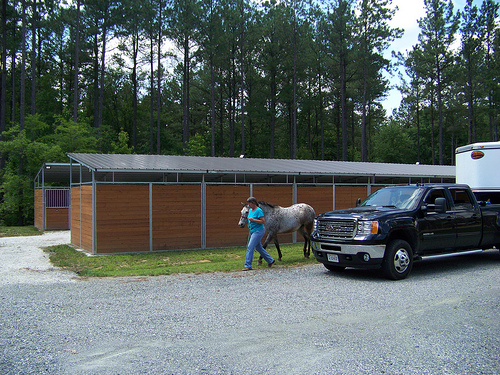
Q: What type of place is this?
A: It is a road.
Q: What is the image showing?
A: It is showing a road.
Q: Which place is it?
A: It is a road.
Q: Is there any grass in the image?
A: Yes, there is grass.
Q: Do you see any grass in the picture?
A: Yes, there is grass.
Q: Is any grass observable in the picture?
A: Yes, there is grass.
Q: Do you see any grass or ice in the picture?
A: Yes, there is grass.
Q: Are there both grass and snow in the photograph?
A: No, there is grass but no snow.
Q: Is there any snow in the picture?
A: No, there is no snow.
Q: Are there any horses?
A: Yes, there is a horse.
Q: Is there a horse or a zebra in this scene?
A: Yes, there is a horse.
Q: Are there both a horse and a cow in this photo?
A: No, there is a horse but no cows.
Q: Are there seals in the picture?
A: No, there are no seals.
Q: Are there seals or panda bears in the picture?
A: No, there are no seals or panda bears.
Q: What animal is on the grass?
A: The animal is a horse.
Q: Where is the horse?
A: The horse is on the grass.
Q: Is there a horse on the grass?
A: Yes, there is a horse on the grass.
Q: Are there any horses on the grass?
A: Yes, there is a horse on the grass.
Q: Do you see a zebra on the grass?
A: No, there is a horse on the grass.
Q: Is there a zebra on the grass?
A: No, there is a horse on the grass.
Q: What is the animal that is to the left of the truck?
A: The animal is a horse.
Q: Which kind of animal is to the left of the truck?
A: The animal is a horse.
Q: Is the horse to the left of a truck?
A: Yes, the horse is to the left of a truck.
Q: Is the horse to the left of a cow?
A: No, the horse is to the left of a truck.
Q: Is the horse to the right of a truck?
A: No, the horse is to the left of a truck.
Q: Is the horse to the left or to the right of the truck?
A: The horse is to the left of the truck.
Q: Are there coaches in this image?
A: No, there are no coaches.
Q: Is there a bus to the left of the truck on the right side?
A: No, there is a man to the left of the truck.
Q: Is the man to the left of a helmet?
A: No, the man is to the left of the truck.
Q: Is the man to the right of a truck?
A: No, the man is to the left of a truck.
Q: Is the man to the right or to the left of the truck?
A: The man is to the left of the truck.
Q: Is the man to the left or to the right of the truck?
A: The man is to the left of the truck.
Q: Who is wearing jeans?
A: The man is wearing jeans.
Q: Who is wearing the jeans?
A: The man is wearing jeans.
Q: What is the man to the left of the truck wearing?
A: The man is wearing jeans.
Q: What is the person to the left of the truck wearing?
A: The man is wearing jeans.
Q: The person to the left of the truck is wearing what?
A: The man is wearing jeans.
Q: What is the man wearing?
A: The man is wearing jeans.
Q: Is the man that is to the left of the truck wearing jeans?
A: Yes, the man is wearing jeans.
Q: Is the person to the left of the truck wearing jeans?
A: Yes, the man is wearing jeans.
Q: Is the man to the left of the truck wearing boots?
A: No, the man is wearing jeans.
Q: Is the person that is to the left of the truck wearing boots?
A: No, the man is wearing jeans.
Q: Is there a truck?
A: Yes, there is a truck.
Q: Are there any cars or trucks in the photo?
A: Yes, there is a truck.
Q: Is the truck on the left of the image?
A: No, the truck is on the right of the image.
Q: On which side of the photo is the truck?
A: The truck is on the right of the image.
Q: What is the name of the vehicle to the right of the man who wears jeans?
A: The vehicle is a truck.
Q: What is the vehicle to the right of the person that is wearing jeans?
A: The vehicle is a truck.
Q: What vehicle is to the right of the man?
A: The vehicle is a truck.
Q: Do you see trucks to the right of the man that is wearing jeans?
A: Yes, there is a truck to the right of the man.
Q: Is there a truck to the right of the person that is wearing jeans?
A: Yes, there is a truck to the right of the man.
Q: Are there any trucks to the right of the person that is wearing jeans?
A: Yes, there is a truck to the right of the man.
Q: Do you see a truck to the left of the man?
A: No, the truck is to the right of the man.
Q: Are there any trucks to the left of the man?
A: No, the truck is to the right of the man.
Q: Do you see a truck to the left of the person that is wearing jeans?
A: No, the truck is to the right of the man.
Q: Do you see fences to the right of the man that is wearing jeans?
A: No, there is a truck to the right of the man.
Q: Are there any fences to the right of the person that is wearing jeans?
A: No, there is a truck to the right of the man.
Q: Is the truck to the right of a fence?
A: No, the truck is to the right of a man.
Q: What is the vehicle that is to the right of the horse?
A: The vehicle is a truck.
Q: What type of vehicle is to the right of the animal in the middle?
A: The vehicle is a truck.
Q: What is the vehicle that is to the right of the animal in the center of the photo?
A: The vehicle is a truck.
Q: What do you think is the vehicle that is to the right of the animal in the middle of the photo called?
A: The vehicle is a truck.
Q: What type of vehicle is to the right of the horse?
A: The vehicle is a truck.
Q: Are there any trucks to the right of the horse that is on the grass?
A: Yes, there is a truck to the right of the horse.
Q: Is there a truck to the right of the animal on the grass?
A: Yes, there is a truck to the right of the horse.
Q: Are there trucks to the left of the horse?
A: No, the truck is to the right of the horse.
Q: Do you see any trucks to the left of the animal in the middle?
A: No, the truck is to the right of the horse.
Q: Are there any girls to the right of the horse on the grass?
A: No, there is a truck to the right of the horse.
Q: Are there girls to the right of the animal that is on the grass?
A: No, there is a truck to the right of the horse.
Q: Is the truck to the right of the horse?
A: Yes, the truck is to the right of the horse.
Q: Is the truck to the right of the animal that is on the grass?
A: Yes, the truck is to the right of the horse.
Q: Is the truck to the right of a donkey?
A: No, the truck is to the right of the horse.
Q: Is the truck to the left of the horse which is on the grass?
A: No, the truck is to the right of the horse.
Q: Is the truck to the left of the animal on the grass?
A: No, the truck is to the right of the horse.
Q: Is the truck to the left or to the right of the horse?
A: The truck is to the right of the horse.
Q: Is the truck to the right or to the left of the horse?
A: The truck is to the right of the horse.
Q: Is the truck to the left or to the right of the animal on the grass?
A: The truck is to the right of the horse.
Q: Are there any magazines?
A: No, there are no magazines.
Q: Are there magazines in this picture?
A: No, there are no magazines.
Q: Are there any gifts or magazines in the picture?
A: No, there are no magazines or gifts.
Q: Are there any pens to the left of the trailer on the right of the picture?
A: Yes, there are pens to the left of the trailer.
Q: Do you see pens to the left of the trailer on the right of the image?
A: Yes, there are pens to the left of the trailer.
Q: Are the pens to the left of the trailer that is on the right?
A: Yes, the pens are to the left of the trailer.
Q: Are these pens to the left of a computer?
A: No, the pens are to the left of the trailer.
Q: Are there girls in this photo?
A: No, there are no girls.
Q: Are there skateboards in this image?
A: No, there are no skateboards.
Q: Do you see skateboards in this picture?
A: No, there are no skateboards.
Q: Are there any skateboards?
A: No, there are no skateboards.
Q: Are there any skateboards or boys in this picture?
A: No, there are no skateboards or boys.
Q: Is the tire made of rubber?
A: Yes, the tire is made of rubber.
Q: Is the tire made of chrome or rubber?
A: The tire is made of rubber.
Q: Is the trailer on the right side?
A: Yes, the trailer is on the right of the image.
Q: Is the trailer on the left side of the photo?
A: No, the trailer is on the right of the image.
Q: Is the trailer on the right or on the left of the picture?
A: The trailer is on the right of the image.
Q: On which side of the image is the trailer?
A: The trailer is on the right of the image.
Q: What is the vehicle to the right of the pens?
A: The vehicle is a trailer.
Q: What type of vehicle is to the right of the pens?
A: The vehicle is a trailer.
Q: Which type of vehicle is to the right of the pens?
A: The vehicle is a trailer.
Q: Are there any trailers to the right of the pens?
A: Yes, there is a trailer to the right of the pens.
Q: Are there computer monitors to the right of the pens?
A: No, there is a trailer to the right of the pens.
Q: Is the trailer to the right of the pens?
A: Yes, the trailer is to the right of the pens.